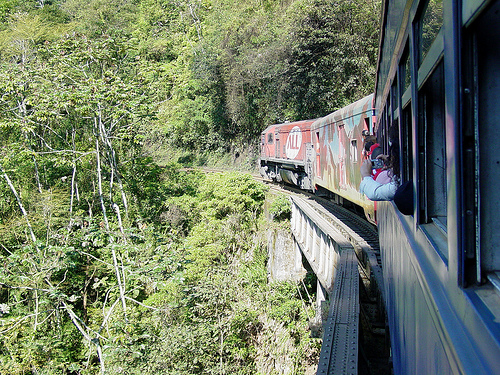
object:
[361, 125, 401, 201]
person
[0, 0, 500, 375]
picture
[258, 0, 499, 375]
train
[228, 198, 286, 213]
foliage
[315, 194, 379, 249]
track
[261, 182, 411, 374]
bridge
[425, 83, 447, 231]
window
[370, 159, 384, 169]
camera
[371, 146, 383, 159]
cap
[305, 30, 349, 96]
tree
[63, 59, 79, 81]
branch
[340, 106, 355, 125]
painting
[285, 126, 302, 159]
circle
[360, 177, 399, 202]
sleeve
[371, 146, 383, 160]
head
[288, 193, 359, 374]
fence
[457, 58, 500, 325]
door